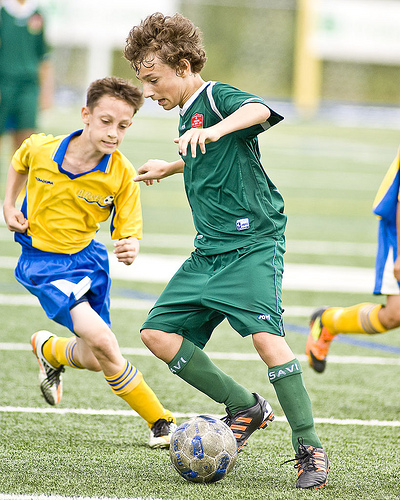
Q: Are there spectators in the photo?
A: No, there are no spectators.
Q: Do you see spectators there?
A: No, there are no spectators.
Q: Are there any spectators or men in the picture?
A: No, there are no spectators or men.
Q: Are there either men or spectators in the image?
A: No, there are no spectators or men.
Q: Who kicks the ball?
A: The boy kicks the ball.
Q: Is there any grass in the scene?
A: Yes, there is grass.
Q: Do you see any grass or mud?
A: Yes, there is grass.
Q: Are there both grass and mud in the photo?
A: No, there is grass but no mud.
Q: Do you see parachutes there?
A: No, there are no parachutes.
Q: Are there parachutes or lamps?
A: No, there are no parachutes or lamps.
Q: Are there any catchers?
A: No, there are no catchers.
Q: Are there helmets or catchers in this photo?
A: No, there are no catchers or helmets.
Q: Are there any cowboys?
A: No, there are no cowboys.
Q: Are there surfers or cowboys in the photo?
A: No, there are no cowboys or surfers.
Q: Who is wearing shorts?
A: The boy is wearing shorts.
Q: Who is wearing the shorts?
A: The boy is wearing shorts.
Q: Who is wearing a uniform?
A: The boy is wearing a uniform.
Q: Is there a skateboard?
A: No, there are no skateboards.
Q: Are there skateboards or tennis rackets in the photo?
A: No, there are no skateboards or tennis rackets.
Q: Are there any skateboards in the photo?
A: No, there are no skateboards.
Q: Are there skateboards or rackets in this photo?
A: No, there are no skateboards or rackets.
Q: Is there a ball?
A: Yes, there is a ball.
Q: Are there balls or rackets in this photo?
A: Yes, there is a ball.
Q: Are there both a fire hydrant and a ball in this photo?
A: No, there is a ball but no fire hydrants.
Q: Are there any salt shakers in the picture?
A: No, there are no salt shakers.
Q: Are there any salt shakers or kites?
A: No, there are no salt shakers or kites.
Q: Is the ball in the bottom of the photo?
A: Yes, the ball is in the bottom of the image.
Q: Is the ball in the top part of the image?
A: No, the ball is in the bottom of the image.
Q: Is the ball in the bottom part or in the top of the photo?
A: The ball is in the bottom of the image.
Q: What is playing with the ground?
A: The ball is playing with the ground.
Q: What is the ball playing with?
A: The ball is playing with the ground.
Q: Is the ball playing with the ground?
A: Yes, the ball is playing with the ground.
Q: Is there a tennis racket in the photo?
A: No, there are no rackets.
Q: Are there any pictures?
A: No, there are no pictures.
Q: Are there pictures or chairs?
A: No, there are no pictures or chairs.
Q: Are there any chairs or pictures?
A: No, there are no pictures or chairs.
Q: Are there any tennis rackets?
A: No, there are no tennis rackets.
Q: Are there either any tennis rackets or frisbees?
A: No, there are no tennis rackets or frisbees.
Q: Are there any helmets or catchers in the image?
A: No, there are no catchers or helmets.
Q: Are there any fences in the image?
A: Yes, there is a fence.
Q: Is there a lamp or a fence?
A: Yes, there is a fence.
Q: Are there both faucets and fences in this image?
A: No, there is a fence but no faucets.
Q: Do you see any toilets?
A: No, there are no toilets.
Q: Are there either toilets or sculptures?
A: No, there are no toilets or sculptures.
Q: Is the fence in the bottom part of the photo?
A: Yes, the fence is in the bottom of the image.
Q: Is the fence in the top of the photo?
A: No, the fence is in the bottom of the image.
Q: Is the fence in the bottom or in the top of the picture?
A: The fence is in the bottom of the image.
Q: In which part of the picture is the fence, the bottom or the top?
A: The fence is in the bottom of the image.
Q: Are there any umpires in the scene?
A: No, there are no umpires.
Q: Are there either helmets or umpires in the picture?
A: No, there are no umpires or helmets.